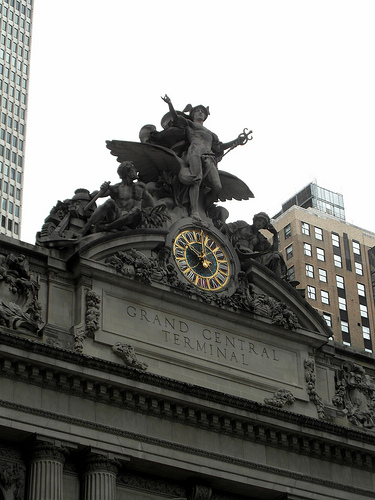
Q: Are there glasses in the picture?
A: No, there are no glasses.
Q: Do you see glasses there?
A: No, there are no glasses.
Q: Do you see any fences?
A: No, there are no fences.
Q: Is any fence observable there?
A: No, there are no fences.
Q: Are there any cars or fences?
A: No, there are no fences or cars.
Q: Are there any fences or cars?
A: No, there are no fences or cars.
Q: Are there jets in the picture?
A: No, there are no jets.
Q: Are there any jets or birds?
A: No, there are no jets or birds.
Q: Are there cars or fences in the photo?
A: No, there are no cars or fences.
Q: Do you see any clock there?
A: Yes, there is a clock.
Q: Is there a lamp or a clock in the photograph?
A: Yes, there is a clock.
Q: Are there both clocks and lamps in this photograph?
A: No, there is a clock but no lamps.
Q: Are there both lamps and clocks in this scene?
A: No, there is a clock but no lamps.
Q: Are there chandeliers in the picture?
A: No, there are no chandeliers.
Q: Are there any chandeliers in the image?
A: No, there are no chandeliers.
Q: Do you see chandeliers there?
A: No, there are no chandeliers.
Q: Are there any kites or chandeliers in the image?
A: No, there are no chandeliers or kites.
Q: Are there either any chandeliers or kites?
A: No, there are no chandeliers or kites.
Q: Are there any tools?
A: No, there are no tools.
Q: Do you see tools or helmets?
A: No, there are no tools or helmets.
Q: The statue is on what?
A: The statue is on the building.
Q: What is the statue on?
A: The statue is on the building.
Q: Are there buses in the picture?
A: No, there are no buses.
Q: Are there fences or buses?
A: No, there are no buses or fences.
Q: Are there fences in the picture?
A: No, there are no fences.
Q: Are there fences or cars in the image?
A: No, there are no fences or cars.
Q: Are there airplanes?
A: No, there are no airplanes.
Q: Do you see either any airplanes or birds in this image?
A: No, there are no airplanes or birds.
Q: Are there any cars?
A: No, there are no cars.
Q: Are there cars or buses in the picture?
A: No, there are no cars or buses.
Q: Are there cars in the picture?
A: No, there are no cars.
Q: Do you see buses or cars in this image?
A: No, there are no cars or buses.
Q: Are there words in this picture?
A: Yes, there are words.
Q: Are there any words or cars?
A: Yes, there are words.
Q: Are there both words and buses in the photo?
A: No, there are words but no buses.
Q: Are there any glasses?
A: No, there are no glasses.